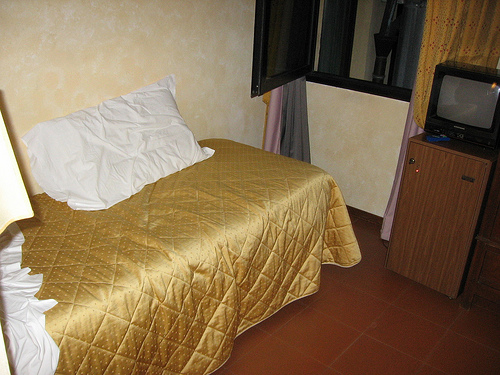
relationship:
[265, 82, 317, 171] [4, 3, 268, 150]
curtain on wall